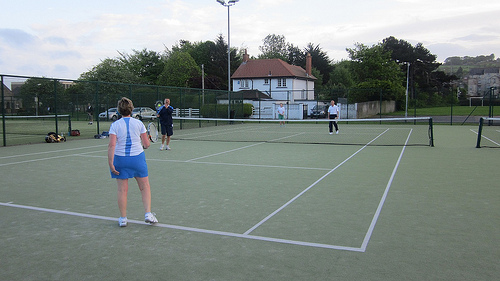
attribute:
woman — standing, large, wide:
[92, 82, 175, 231]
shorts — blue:
[114, 156, 152, 184]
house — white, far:
[232, 49, 320, 111]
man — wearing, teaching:
[151, 96, 193, 152]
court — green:
[223, 131, 374, 272]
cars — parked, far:
[95, 102, 123, 130]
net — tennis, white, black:
[222, 111, 285, 152]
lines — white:
[313, 161, 343, 197]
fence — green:
[22, 80, 107, 133]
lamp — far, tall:
[212, 0, 247, 35]